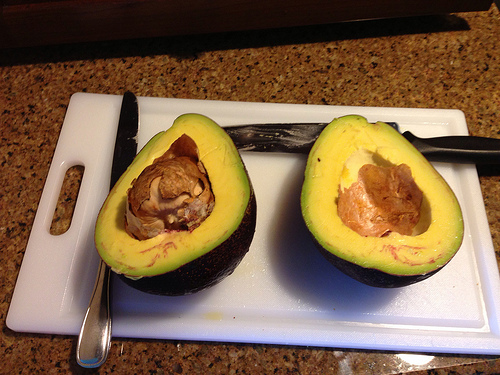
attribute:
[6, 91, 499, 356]
cutting board — white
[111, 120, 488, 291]
avocado — ripe 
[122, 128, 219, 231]
meat — green, yellow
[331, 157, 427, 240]
meat — yellow, green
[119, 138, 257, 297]
avocado skin — dark green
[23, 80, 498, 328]
cutting board — plastic, white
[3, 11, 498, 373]
counter — granite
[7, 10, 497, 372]
countertop — granite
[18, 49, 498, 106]
countertop — granite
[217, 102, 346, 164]
knife — stained 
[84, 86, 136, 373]
knife — yellow, green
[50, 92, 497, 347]
board — white, cutting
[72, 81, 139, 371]
knife — case, silvery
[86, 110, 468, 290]
avocado — cut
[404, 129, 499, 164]
handle — knife, black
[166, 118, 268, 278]
avocado — cut in half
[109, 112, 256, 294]
avocado — half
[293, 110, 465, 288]
avocado — other half, yellow-green, black-peeled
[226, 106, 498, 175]
knife — sharp 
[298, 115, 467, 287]
meat — inside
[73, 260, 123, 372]
handle — silver 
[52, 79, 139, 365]
butter knife — thick, silver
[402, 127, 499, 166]
handle — black